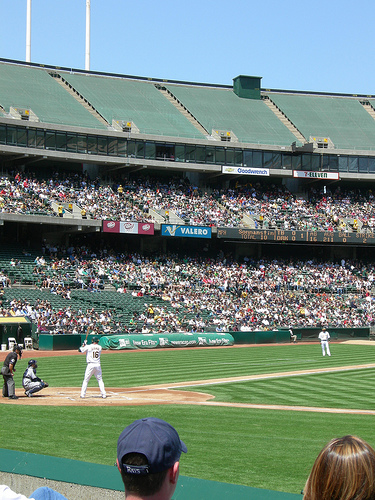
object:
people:
[0, 171, 375, 235]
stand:
[8, 209, 370, 250]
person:
[116, 418, 188, 500]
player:
[318, 327, 331, 356]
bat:
[82, 328, 89, 348]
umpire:
[0, 335, 27, 403]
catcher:
[22, 359, 49, 396]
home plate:
[42, 392, 170, 402]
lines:
[153, 365, 374, 395]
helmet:
[28, 359, 36, 367]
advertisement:
[97, 332, 234, 351]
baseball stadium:
[0, 57, 375, 351]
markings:
[108, 392, 138, 403]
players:
[1, 343, 8, 353]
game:
[218, 226, 375, 246]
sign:
[157, 221, 216, 244]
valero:
[175, 227, 209, 235]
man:
[288, 327, 297, 342]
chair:
[290, 334, 292, 342]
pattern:
[168, 367, 375, 412]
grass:
[132, 358, 344, 446]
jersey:
[79, 343, 102, 364]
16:
[93, 351, 99, 358]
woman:
[303, 435, 375, 500]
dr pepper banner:
[103, 220, 155, 235]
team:
[302, 327, 373, 404]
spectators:
[13, 430, 373, 497]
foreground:
[0, 338, 375, 500]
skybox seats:
[6, 59, 370, 178]